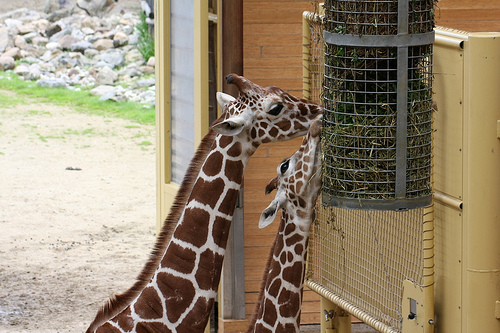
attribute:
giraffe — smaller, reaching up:
[248, 109, 330, 333]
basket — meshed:
[321, 0, 432, 210]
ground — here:
[0, 88, 155, 331]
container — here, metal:
[322, 2, 434, 204]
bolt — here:
[424, 319, 434, 327]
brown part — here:
[202, 151, 223, 175]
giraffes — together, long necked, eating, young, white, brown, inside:
[84, 73, 331, 331]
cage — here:
[318, 0, 436, 211]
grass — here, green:
[325, 3, 431, 196]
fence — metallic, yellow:
[305, 6, 432, 331]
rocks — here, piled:
[1, 0, 156, 106]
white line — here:
[138, 1, 154, 19]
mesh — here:
[324, 2, 431, 198]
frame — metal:
[297, 11, 436, 331]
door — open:
[157, 2, 206, 243]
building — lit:
[147, 2, 497, 333]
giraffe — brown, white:
[99, 80, 321, 329]